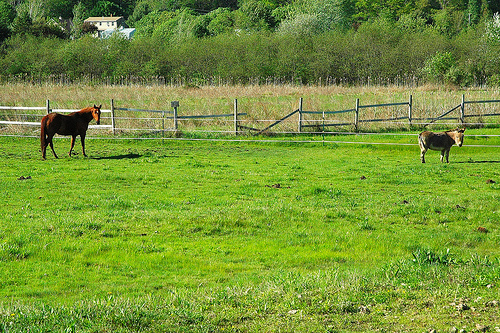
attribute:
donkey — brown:
[414, 125, 469, 163]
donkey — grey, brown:
[412, 120, 462, 157]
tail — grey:
[417, 135, 431, 158]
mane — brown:
[73, 104, 93, 114]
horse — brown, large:
[32, 101, 102, 159]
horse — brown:
[34, 98, 108, 165]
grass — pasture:
[219, 236, 483, 302]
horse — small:
[417, 124, 467, 161]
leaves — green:
[174, 41, 316, 66]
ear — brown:
[89, 102, 99, 112]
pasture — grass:
[2, 129, 499, 331]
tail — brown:
[38, 112, 49, 150]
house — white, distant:
[85, 15, 137, 36]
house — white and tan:
[82, 16, 134, 38]